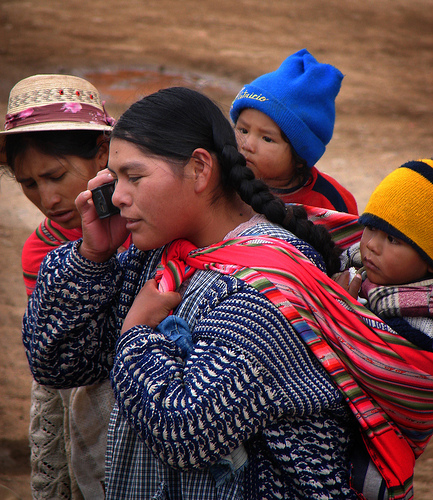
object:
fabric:
[150, 236, 433, 480]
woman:
[24, 84, 374, 500]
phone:
[91, 181, 119, 220]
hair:
[110, 81, 354, 276]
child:
[225, 50, 361, 223]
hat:
[229, 50, 344, 163]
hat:
[0, 67, 111, 165]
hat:
[353, 156, 432, 267]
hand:
[73, 162, 129, 258]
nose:
[112, 178, 133, 208]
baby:
[331, 160, 432, 461]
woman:
[0, 73, 152, 500]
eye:
[130, 175, 147, 184]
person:
[26, 87, 343, 500]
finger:
[74, 189, 92, 212]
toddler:
[335, 151, 433, 443]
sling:
[140, 197, 431, 492]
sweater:
[21, 219, 371, 498]